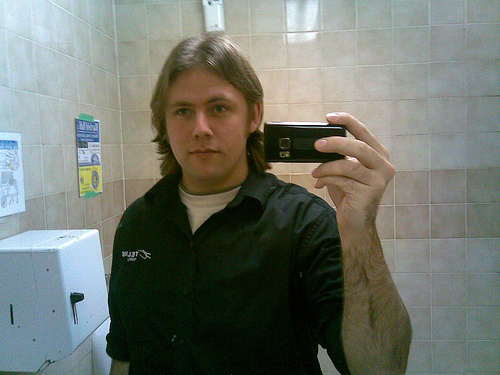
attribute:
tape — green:
[77, 113, 95, 123]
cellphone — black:
[259, 117, 353, 167]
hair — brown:
[351, 233, 396, 327]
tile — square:
[464, 168, 499, 203]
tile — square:
[468, 130, 498, 167]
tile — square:
[393, 135, 429, 170]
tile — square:
[429, 240, 466, 276]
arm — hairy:
[294, 123, 474, 373]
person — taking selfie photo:
[95, 19, 486, 373]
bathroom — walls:
[0, 2, 498, 372]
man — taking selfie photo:
[92, 32, 431, 373]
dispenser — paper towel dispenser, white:
[0, 221, 109, 364]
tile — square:
[423, 57, 475, 107]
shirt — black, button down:
[105, 170, 350, 373]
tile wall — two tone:
[350, 0, 492, 127]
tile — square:
[430, 167, 466, 202]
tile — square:
[430, 24, 465, 60]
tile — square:
[428, 60, 465, 97]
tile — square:
[430, 95, 465, 130]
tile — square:
[430, 130, 467, 167]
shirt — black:
[105, 179, 308, 371]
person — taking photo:
[95, 35, 412, 372]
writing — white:
[119, 247, 153, 262]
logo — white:
[113, 235, 161, 276]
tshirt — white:
[111, 178, 341, 373]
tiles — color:
[401, 144, 476, 236]